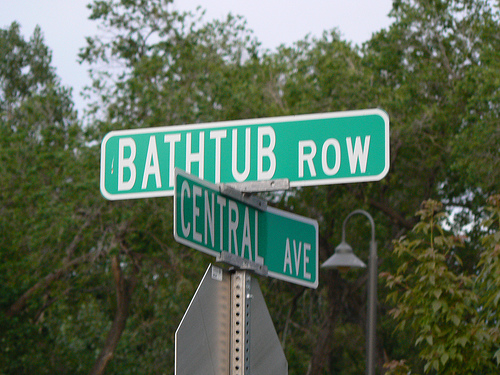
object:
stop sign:
[174, 261, 289, 374]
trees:
[1, 21, 113, 375]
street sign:
[97, 108, 392, 203]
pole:
[229, 267, 253, 375]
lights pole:
[364, 239, 380, 374]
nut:
[246, 293, 253, 300]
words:
[297, 135, 371, 179]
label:
[211, 264, 223, 282]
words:
[179, 179, 265, 266]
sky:
[1, 0, 499, 157]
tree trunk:
[94, 250, 129, 374]